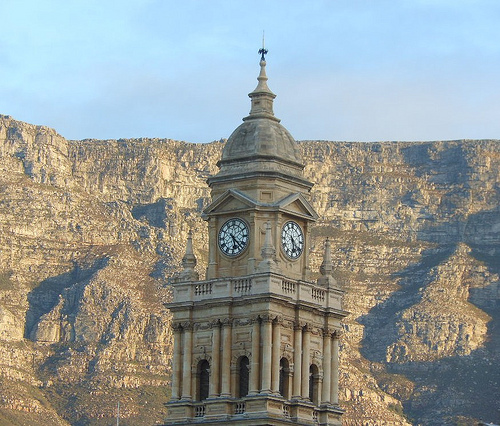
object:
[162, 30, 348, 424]
building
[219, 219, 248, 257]
clock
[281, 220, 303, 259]
clock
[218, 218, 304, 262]
clocks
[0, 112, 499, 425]
mountains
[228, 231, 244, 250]
hands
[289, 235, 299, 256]
hands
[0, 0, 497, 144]
sky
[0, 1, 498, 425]
photo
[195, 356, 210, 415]
archway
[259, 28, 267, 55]
tip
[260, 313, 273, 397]
pillar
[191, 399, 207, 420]
railing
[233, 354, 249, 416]
archway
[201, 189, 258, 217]
triangle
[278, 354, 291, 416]
archway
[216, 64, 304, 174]
dome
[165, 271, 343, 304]
parapet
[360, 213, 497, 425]
shadow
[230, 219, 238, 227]
roman numeral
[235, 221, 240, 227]
roman numeral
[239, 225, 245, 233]
roman numeral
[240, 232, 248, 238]
roman numeral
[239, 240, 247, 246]
roman numeral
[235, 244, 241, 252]
roman numeral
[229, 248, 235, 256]
roman numeral